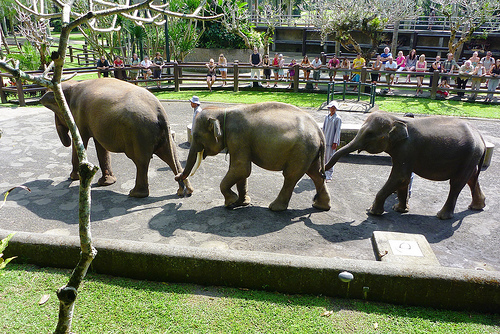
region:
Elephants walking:
[42, 74, 442, 242]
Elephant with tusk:
[171, 83, 321, 198]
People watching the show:
[171, 21, 469, 123]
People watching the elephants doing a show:
[56, 46, 402, 263]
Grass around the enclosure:
[109, 275, 166, 306]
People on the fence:
[134, 58, 326, 90]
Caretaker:
[307, 101, 370, 190]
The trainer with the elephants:
[177, 86, 229, 190]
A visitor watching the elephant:
[129, 34, 181, 108]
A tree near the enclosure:
[43, 30, 114, 315]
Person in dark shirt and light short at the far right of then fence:
[488, 53, 498, 104]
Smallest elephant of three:
[322, 91, 491, 244]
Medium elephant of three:
[177, 74, 336, 234]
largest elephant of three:
[46, 58, 198, 233]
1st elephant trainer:
[185, 94, 204, 162]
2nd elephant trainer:
[320, 92, 342, 182]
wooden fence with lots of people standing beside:
[0, 63, 499, 105]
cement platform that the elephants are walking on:
[12, 116, 497, 252]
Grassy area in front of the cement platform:
[0, 267, 497, 332]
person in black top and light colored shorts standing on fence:
[248, 27, 262, 82]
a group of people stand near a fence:
[103, 38, 496, 98]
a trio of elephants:
[35, 68, 494, 252]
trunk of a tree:
[53, 13, 76, 332]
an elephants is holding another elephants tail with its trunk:
[317, 98, 491, 228]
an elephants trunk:
[323, 135, 365, 182]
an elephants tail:
[311, 130, 331, 180]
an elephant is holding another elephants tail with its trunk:
[168, 93, 340, 219]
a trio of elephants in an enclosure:
[20, 49, 498, 249]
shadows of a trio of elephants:
[0, 173, 483, 250]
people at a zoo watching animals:
[88, 50, 498, 105]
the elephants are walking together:
[36, 61, 498, 246]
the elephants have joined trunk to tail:
[21, 47, 479, 242]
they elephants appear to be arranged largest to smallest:
[13, 58, 498, 239]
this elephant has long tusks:
[171, 115, 223, 212]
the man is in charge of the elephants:
[166, 88, 212, 140]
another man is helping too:
[322, 81, 351, 163]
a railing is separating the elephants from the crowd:
[8, 11, 488, 100]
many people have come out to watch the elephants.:
[88, 3, 489, 85]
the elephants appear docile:
[33, 45, 499, 236]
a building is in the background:
[139, 1, 471, 50]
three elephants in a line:
[35, 69, 497, 219]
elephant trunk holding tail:
[314, 143, 345, 180]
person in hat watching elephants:
[313, 102, 342, 166]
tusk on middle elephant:
[187, 143, 208, 185]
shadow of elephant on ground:
[143, 199, 320, 245]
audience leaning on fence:
[269, 53, 409, 85]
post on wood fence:
[228, 58, 244, 90]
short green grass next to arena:
[117, 288, 237, 319]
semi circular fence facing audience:
[321, 76, 379, 108]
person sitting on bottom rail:
[198, 56, 220, 96]